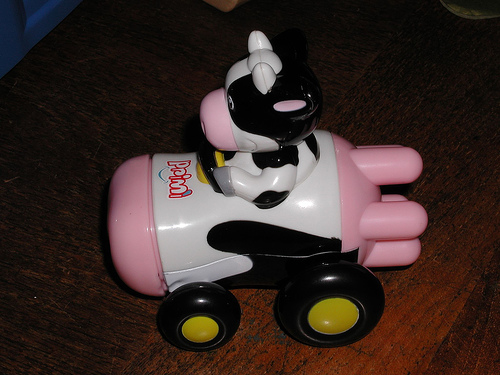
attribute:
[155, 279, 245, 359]
wheel — black, yellow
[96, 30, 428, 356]
toy — black, white, pink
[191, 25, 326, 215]
driver — cow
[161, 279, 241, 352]
tire — smaller, toy's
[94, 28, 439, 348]
cow — pink nose., white spot , head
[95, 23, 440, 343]
car — toy, Cow , pink utters., Yellow middle section 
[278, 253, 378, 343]
car — Black wheel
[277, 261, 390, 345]
car — Black wheel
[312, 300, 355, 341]
tire — Yellow middle section 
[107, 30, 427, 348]
child's toy — cow themed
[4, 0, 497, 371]
surface — Wooden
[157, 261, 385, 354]
tires — black, yellow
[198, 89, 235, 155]
cow's nose — pink